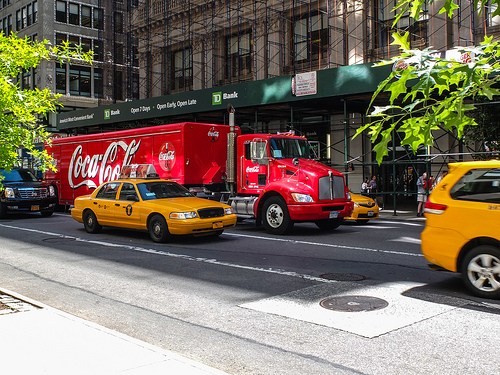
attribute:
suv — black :
[1, 164, 56, 220]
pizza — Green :
[179, 243, 274, 305]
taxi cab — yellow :
[66, 178, 236, 248]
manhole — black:
[318, 289, 396, 312]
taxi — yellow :
[350, 188, 385, 225]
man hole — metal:
[316, 294, 392, 314]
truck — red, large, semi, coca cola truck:
[42, 107, 354, 235]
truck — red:
[43, 122, 355, 234]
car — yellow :
[417, 153, 499, 289]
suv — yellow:
[420, 158, 498, 300]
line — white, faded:
[99, 195, 369, 326]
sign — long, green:
[57, 54, 415, 129]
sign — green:
[57, 45, 495, 127]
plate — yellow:
[174, 204, 241, 238]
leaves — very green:
[1, 32, 94, 182]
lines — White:
[222, 259, 254, 268]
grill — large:
[314, 167, 354, 202]